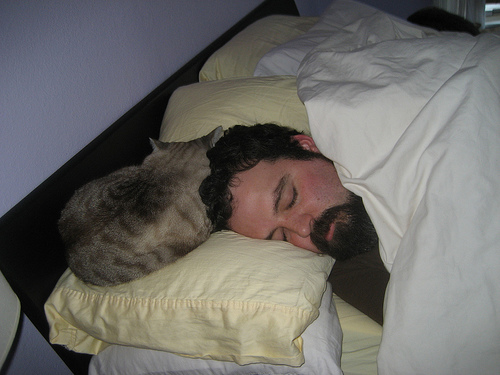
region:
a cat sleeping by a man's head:
[55, 124, 223, 292]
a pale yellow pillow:
[46, 73, 366, 367]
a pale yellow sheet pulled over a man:
[264, 1, 499, 373]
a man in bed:
[199, 121, 380, 262]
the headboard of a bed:
[0, 0, 300, 372]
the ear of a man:
[292, 130, 318, 153]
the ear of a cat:
[205, 120, 225, 143]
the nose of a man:
[282, 211, 314, 236]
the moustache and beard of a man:
[310, 201, 375, 261]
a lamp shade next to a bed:
[1, 272, 22, 373]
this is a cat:
[46, 92, 250, 318]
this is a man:
[186, 110, 404, 296]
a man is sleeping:
[137, 65, 499, 372]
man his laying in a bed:
[118, 56, 498, 333]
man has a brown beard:
[318, 198, 378, 258]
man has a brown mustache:
[294, 199, 343, 244]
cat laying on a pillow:
[65, 47, 342, 366]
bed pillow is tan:
[55, 74, 342, 362]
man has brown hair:
[180, 116, 297, 218]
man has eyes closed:
[254, 173, 316, 250]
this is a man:
[229, 112, 379, 247]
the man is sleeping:
[227, 107, 377, 234]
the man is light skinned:
[304, 164, 335, 196]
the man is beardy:
[347, 208, 367, 251]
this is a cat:
[63, 135, 206, 281]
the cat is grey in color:
[167, 180, 194, 221]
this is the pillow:
[204, 252, 301, 334]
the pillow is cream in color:
[222, 249, 307, 327]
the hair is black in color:
[244, 124, 288, 150]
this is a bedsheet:
[377, 58, 474, 158]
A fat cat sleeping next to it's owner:
[57, 126, 225, 288]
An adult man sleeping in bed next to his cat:
[199, 123, 391, 327]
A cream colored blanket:
[296, 13, 497, 370]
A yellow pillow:
[198, 14, 318, 81]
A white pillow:
[87, 281, 342, 373]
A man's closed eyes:
[268, 182, 296, 239]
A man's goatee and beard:
[311, 203, 378, 260]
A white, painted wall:
[1, 2, 262, 372]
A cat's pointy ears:
[150, 126, 225, 156]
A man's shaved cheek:
[305, 160, 351, 204]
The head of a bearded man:
[205, 119, 375, 261]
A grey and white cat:
[57, 125, 218, 285]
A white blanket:
[252, 2, 497, 372]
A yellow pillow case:
[43, 75, 335, 370]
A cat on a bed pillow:
[44, 78, 336, 367]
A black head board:
[0, 1, 302, 373]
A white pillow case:
[83, 282, 343, 373]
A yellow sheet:
[331, 291, 384, 373]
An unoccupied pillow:
[197, 14, 325, 80]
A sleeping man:
[197, 121, 389, 326]